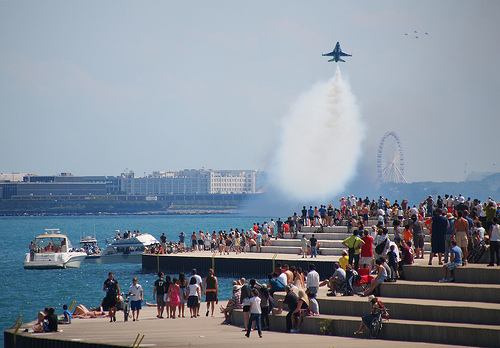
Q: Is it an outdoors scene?
A: Yes, it is outdoors.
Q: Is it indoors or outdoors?
A: It is outdoors.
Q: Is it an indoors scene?
A: No, it is outdoors.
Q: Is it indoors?
A: No, it is outdoors.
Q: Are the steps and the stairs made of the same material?
A: Yes, both the steps and the stairs are made of cement.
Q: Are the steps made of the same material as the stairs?
A: Yes, both the steps and the stairs are made of cement.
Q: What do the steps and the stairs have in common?
A: The material, both the steps and the stairs are concrete.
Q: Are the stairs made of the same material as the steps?
A: Yes, both the stairs and the steps are made of cement.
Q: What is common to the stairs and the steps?
A: The material, both the stairs and the steps are concrete.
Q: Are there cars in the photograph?
A: No, there are no cars.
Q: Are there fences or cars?
A: No, there are no cars or fences.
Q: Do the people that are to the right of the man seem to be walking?
A: Yes, the people are walking.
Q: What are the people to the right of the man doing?
A: The people are walking.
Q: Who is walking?
A: The people are walking.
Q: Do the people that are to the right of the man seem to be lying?
A: No, the people are walking.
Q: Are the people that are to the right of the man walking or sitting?
A: The people are walking.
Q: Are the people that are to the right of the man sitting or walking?
A: The people are walking.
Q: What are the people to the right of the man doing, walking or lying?
A: The people are walking.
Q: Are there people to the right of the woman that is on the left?
A: Yes, there are people to the right of the woman.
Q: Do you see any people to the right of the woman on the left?
A: Yes, there are people to the right of the woman.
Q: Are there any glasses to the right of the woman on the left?
A: No, there are people to the right of the woman.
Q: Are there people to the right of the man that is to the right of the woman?
A: Yes, there are people to the right of the man.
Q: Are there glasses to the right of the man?
A: No, there are people to the right of the man.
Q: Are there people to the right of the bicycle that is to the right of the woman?
A: Yes, there are people to the right of the bicycle.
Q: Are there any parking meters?
A: No, there are no parking meters.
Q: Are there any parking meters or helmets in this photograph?
A: No, there are no parking meters or helmets.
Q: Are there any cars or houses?
A: No, there are no houses or cars.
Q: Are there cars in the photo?
A: No, there are no cars.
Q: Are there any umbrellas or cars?
A: No, there are no cars or umbrellas.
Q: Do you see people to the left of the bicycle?
A: Yes, there are people to the left of the bicycle.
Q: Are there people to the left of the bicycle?
A: Yes, there are people to the left of the bicycle.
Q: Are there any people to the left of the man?
A: Yes, there are people to the left of the man.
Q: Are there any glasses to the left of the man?
A: No, there are people to the left of the man.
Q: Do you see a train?
A: No, there are no trains.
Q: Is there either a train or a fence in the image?
A: No, there are no trains or fences.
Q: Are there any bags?
A: No, there are no bags.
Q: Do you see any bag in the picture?
A: No, there are no bags.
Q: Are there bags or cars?
A: No, there are no bags or cars.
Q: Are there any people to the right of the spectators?
A: Yes, there are people to the right of the spectators.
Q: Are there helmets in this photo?
A: No, there are no helmets.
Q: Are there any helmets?
A: No, there are no helmets.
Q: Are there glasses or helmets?
A: No, there are no helmets or glasses.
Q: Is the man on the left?
A: Yes, the man is on the left of the image.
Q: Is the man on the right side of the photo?
A: No, the man is on the left of the image.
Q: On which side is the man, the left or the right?
A: The man is on the left of the image.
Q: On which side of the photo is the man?
A: The man is on the left of the image.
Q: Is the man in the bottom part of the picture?
A: Yes, the man is in the bottom of the image.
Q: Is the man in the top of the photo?
A: No, the man is in the bottom of the image.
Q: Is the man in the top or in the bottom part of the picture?
A: The man is in the bottom of the image.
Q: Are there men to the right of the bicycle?
A: Yes, there is a man to the right of the bicycle.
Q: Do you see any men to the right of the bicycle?
A: Yes, there is a man to the right of the bicycle.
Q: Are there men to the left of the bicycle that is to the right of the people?
A: No, the man is to the right of the bicycle.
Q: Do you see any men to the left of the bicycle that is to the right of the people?
A: No, the man is to the right of the bicycle.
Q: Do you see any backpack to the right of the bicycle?
A: No, there is a man to the right of the bicycle.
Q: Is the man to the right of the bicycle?
A: Yes, the man is to the right of the bicycle.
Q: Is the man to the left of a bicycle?
A: No, the man is to the right of a bicycle.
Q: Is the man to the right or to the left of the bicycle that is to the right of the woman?
A: The man is to the right of the bicycle.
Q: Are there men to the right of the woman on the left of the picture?
A: Yes, there is a man to the right of the woman.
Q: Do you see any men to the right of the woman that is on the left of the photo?
A: Yes, there is a man to the right of the woman.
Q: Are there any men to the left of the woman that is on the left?
A: No, the man is to the right of the woman.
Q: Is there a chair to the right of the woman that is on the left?
A: No, there is a man to the right of the woman.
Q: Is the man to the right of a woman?
A: Yes, the man is to the right of a woman.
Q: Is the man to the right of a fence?
A: No, the man is to the right of a woman.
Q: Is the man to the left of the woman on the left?
A: No, the man is to the right of the woman.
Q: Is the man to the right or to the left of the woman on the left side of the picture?
A: The man is to the right of the woman.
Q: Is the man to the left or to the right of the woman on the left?
A: The man is to the right of the woman.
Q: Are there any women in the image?
A: Yes, there is a woman.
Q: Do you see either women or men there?
A: Yes, there is a woman.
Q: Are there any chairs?
A: No, there are no chairs.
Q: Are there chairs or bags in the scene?
A: No, there are no chairs or bags.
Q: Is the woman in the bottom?
A: Yes, the woman is in the bottom of the image.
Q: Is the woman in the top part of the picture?
A: No, the woman is in the bottom of the image.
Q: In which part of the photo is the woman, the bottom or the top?
A: The woman is in the bottom of the image.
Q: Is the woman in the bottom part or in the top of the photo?
A: The woman is in the bottom of the image.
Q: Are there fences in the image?
A: No, there are no fences.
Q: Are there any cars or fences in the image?
A: No, there are no fences or cars.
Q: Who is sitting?
A: The people are sitting.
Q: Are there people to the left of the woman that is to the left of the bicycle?
A: Yes, there are people to the left of the woman.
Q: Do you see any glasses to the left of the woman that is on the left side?
A: No, there are people to the left of the woman.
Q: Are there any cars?
A: No, there are no cars.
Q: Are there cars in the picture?
A: No, there are no cars.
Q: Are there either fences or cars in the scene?
A: No, there are no cars or fences.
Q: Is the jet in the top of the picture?
A: Yes, the jet is in the top of the image.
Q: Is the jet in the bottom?
A: No, the jet is in the top of the image.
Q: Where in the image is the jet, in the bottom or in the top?
A: The jet is in the top of the image.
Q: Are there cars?
A: No, there are no cars.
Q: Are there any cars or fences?
A: No, there are no cars or fences.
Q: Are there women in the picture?
A: Yes, there is a woman.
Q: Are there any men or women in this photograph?
A: Yes, there is a woman.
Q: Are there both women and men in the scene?
A: Yes, there are both a woman and a man.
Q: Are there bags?
A: No, there are no bags.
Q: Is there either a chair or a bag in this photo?
A: No, there are no bags or chairs.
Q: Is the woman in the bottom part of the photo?
A: Yes, the woman is in the bottom of the image.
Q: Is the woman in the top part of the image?
A: No, the woman is in the bottom of the image.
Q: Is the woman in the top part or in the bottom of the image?
A: The woman is in the bottom of the image.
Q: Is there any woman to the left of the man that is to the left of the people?
A: Yes, there is a woman to the left of the man.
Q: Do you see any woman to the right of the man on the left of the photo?
A: No, the woman is to the left of the man.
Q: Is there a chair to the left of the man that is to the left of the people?
A: No, there is a woman to the left of the man.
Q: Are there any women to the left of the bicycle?
A: Yes, there is a woman to the left of the bicycle.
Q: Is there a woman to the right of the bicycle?
A: No, the woman is to the left of the bicycle.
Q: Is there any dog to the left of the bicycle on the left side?
A: No, there is a woman to the left of the bicycle.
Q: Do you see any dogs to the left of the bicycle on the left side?
A: No, there is a woman to the left of the bicycle.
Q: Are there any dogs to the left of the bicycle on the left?
A: No, there is a woman to the left of the bicycle.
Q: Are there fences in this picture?
A: No, there are no fences.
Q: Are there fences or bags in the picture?
A: No, there are no fences or bags.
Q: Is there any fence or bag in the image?
A: No, there are no fences or bags.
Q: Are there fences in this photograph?
A: No, there are no fences.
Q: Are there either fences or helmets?
A: No, there are no fences or helmets.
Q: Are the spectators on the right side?
A: Yes, the spectators are on the right of the image.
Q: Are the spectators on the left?
A: No, the spectators are on the right of the image.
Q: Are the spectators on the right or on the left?
A: The spectators are on the right of the image.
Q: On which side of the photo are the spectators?
A: The spectators are on the right of the image.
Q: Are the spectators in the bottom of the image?
A: Yes, the spectators are in the bottom of the image.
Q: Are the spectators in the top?
A: No, the spectators are in the bottom of the image.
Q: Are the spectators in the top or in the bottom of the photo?
A: The spectators are in the bottom of the image.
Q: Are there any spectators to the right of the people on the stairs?
A: Yes, there are spectators to the right of the people.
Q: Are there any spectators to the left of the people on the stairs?
A: No, the spectators are to the right of the people.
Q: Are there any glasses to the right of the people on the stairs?
A: No, there are spectators to the right of the people.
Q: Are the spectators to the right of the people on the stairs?
A: Yes, the spectators are to the right of the people.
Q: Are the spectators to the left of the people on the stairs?
A: No, the spectators are to the right of the people.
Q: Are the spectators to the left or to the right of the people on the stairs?
A: The spectators are to the right of the people.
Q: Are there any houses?
A: No, there are no houses.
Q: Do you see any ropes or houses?
A: No, there are no houses or ropes.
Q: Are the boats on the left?
A: Yes, the boats are on the left of the image.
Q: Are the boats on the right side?
A: No, the boats are on the left of the image.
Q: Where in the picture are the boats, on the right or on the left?
A: The boats are on the left of the image.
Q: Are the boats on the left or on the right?
A: The boats are on the left of the image.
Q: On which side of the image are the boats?
A: The boats are on the left of the image.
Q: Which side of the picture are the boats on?
A: The boats are on the left of the image.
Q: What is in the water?
A: The boats are in the water.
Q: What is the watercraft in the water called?
A: The watercraft is boats.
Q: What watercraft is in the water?
A: The watercraft is boats.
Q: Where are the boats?
A: The boats are in the water.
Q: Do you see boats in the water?
A: Yes, there are boats in the water.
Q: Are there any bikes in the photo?
A: Yes, there is a bike.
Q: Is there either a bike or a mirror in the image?
A: Yes, there is a bike.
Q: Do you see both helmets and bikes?
A: No, there is a bike but no helmets.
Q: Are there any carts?
A: No, there are no carts.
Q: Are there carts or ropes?
A: No, there are no carts or ropes.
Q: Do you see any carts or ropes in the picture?
A: No, there are no carts or ropes.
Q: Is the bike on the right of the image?
A: Yes, the bike is on the right of the image.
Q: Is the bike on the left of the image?
A: No, the bike is on the right of the image.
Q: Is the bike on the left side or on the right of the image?
A: The bike is on the right of the image.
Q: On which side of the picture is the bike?
A: The bike is on the right of the image.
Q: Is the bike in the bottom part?
A: Yes, the bike is in the bottom of the image.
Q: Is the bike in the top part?
A: No, the bike is in the bottom of the image.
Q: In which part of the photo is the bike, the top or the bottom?
A: The bike is in the bottom of the image.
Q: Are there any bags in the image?
A: No, there are no bags.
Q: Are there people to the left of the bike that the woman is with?
A: Yes, there are people to the left of the bike.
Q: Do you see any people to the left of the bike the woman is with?
A: Yes, there are people to the left of the bike.